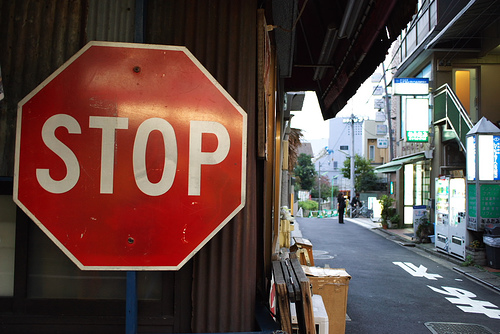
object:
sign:
[11, 39, 243, 273]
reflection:
[115, 98, 243, 136]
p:
[183, 119, 232, 197]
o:
[131, 114, 179, 200]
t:
[86, 115, 130, 195]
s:
[34, 113, 82, 197]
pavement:
[286, 214, 499, 334]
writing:
[391, 257, 499, 320]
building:
[329, 115, 365, 200]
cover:
[421, 320, 491, 332]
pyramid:
[464, 115, 499, 135]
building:
[375, 0, 499, 235]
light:
[403, 162, 425, 225]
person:
[337, 192, 347, 223]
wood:
[271, 250, 314, 334]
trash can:
[483, 220, 499, 268]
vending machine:
[434, 176, 452, 255]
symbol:
[391, 258, 445, 283]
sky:
[302, 112, 323, 140]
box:
[304, 264, 353, 334]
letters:
[34, 113, 232, 199]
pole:
[124, 269, 139, 334]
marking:
[426, 281, 500, 321]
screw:
[133, 65, 142, 73]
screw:
[127, 237, 134, 245]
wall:
[0, 1, 262, 41]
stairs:
[432, 82, 472, 151]